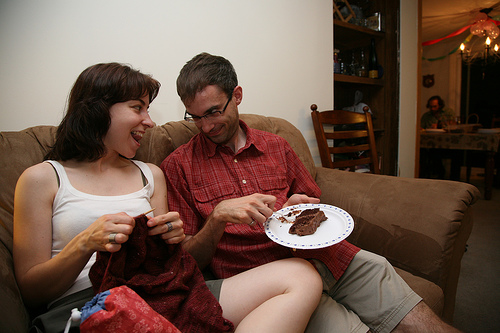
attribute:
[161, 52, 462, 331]
man — looking down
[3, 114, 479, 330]
sofa — brown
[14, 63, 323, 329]
woman — knitting, smiling, crocheting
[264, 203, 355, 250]
plate — white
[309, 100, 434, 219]
chair — brown, wooden, wood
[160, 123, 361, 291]
shirt — buttoned, red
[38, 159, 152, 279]
tank top — white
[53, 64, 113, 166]
hair — brown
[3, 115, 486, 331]
couch — fabric, tan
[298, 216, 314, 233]
desert — chocolate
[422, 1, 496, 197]
room — adjoining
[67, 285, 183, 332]
bag — red, blue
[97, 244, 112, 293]
yarn — balled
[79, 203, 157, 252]
needle — knitting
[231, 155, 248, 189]
buttons — white